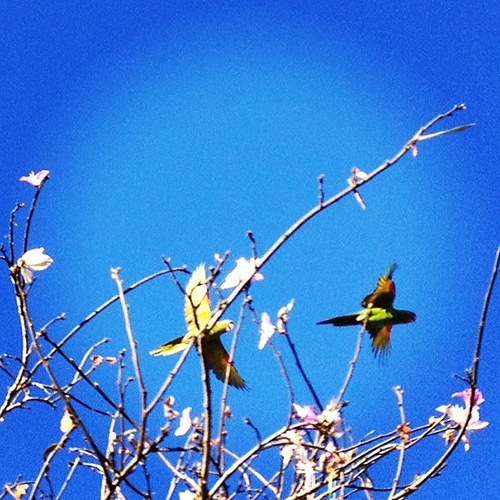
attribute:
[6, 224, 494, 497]
flowers — pink and white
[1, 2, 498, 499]
sky — blue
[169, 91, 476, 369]
branch — brown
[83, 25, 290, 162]
sky — blue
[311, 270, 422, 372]
bird — small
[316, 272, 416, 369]
bird — yellow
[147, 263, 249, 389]
bird — yellow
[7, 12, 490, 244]
sky — blue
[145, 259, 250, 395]
bird — small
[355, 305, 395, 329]
chest feathers — green